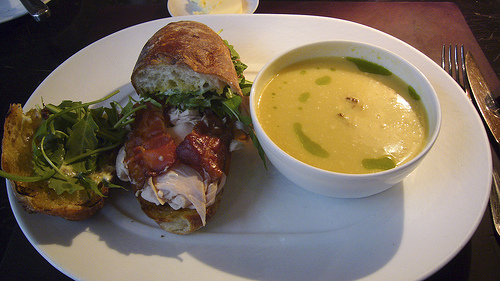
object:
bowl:
[248, 38, 443, 200]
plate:
[0, 13, 495, 281]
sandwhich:
[3, 19, 269, 237]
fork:
[442, 42, 499, 238]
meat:
[136, 165, 209, 226]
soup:
[255, 56, 429, 175]